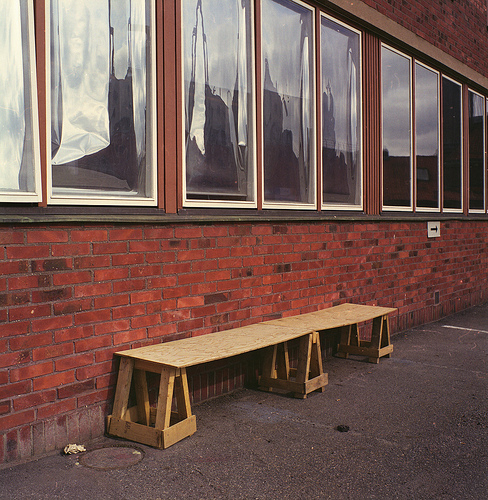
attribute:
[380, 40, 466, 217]
window — clear, glass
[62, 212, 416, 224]
ledge — brown, flat, long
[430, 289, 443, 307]
vent — rectangular, metal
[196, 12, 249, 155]
curtain — white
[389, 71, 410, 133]
sky — cloudy, white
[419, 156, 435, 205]
building — red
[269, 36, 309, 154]
curtain — white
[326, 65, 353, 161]
curtain — white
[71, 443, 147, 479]
cover — round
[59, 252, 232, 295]
wall — brick, high, red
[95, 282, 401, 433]
bench — wooden, brown, plywood, flimsy, make shift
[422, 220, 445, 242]
sign — rectangular, white, black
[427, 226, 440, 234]
arrow — pointing, black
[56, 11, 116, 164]
curtain — white, cloth, short, inside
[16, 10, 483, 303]
building — big, red, long, brick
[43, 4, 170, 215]
window — glass, reflective, brown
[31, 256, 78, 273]
brick — black, red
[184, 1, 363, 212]
window — wide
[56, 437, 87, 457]
trash — brown, paper, crumbled, crumpled, white, black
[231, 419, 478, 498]
concrete — gray, hard, sidewalk, rocky